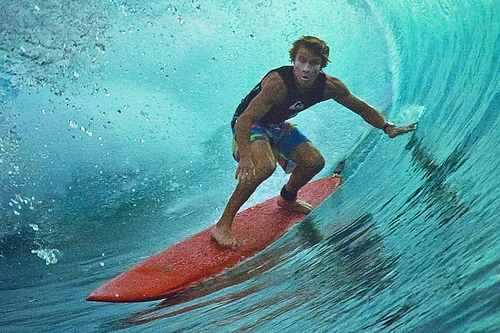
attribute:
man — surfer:
[212, 35, 418, 251]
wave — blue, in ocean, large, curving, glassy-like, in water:
[1, 0, 499, 333]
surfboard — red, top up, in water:
[85, 174, 343, 304]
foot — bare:
[211, 224, 241, 253]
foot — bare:
[277, 196, 314, 214]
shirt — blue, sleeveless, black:
[231, 67, 326, 128]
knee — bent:
[298, 155, 328, 169]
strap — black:
[381, 124, 387, 131]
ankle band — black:
[280, 183, 298, 203]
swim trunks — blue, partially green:
[232, 120, 313, 174]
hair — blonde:
[289, 34, 332, 68]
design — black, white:
[289, 100, 305, 112]